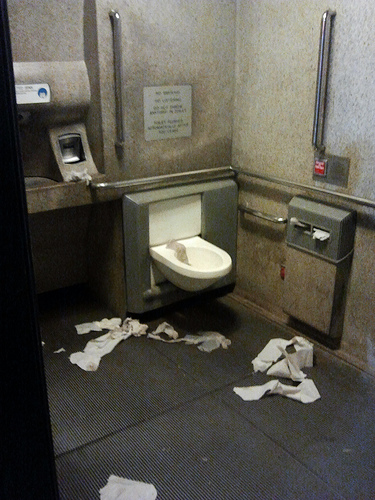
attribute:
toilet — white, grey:
[129, 206, 259, 298]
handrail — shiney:
[237, 203, 288, 225]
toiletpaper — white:
[229, 333, 320, 406]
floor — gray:
[116, 387, 233, 474]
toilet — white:
[148, 231, 237, 295]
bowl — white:
[187, 256, 224, 287]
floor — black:
[164, 432, 200, 481]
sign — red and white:
[310, 153, 326, 178]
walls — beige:
[178, 20, 304, 127]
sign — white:
[143, 83, 196, 140]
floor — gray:
[123, 347, 293, 437]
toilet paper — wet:
[162, 239, 190, 263]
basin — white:
[23, 176, 59, 188]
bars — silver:
[103, 5, 336, 176]